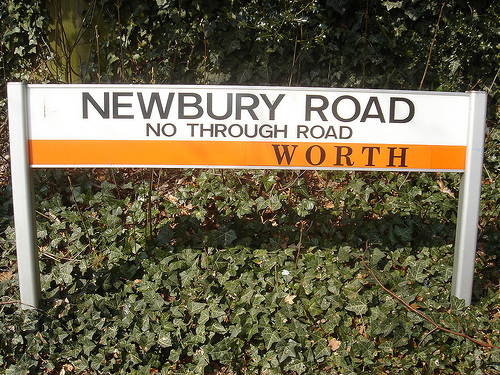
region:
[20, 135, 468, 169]
an orange stripe on the sign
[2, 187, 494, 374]
green leaves on the ground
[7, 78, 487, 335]
a white sign on the ground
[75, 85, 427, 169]
black writing on the sign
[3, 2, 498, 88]
trees behind the sign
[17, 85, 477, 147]
white section on the sign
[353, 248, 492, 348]
long thin brown branch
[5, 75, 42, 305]
a wooden stake in the ground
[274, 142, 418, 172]
WORTH written in black on an orange sign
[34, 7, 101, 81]
sticks behind the sign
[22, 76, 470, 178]
a white sign with black letters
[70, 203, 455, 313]
a shadow cast by the sign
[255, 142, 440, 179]
black letters on the orange area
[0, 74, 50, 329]
a white pole on the left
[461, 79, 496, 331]
a silver pole on the right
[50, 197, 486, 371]
green leaves of plant under sign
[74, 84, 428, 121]
Letters spell Newbury Road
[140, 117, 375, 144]
Letters spell No through Road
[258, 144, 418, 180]
black letters spell Worth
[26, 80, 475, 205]
the sign is white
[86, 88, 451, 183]
the text is black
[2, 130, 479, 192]
it has an orange strip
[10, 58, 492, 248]
the sign is long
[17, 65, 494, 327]
the sign has two posts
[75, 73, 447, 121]
it says newbury road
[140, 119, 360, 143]
it says no through road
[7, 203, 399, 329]
sign is on top of plants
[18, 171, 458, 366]
plants under the sign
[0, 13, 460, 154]
plants are behind the sign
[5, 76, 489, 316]
A road sign explaining that this is not a through road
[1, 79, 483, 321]
A Newberry road sign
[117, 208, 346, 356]
A patch of clovers and other ground greenery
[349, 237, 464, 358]
A stick laying in greenery on the ground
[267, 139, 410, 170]
The word "WORTH" in black against an orange backdrop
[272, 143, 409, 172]
The word "WORTH" in black against an orange background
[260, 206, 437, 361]
A couple of twigs laying in greenery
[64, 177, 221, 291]
A group of bare twigs popping out of ground greenery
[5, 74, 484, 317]
A white, orange, and black street sign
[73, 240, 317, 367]
A parch of various types of ground greenery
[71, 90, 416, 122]
Sign announces 'Newbury road'.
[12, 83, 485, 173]
White and orange signage in vegetation.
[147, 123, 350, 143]
Sign announces that it's a 'no through road'.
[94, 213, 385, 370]
Green ivy ground cover.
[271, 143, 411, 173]
The word, 'worth' on sign.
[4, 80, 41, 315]
White left pole supporting sign.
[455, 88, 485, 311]
White right pole supporting sign.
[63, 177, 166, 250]
Wooden vines among vegetation.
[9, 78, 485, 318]
White sign with orange coloring announcing street.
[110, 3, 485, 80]
Vegetation growing in back of sign.